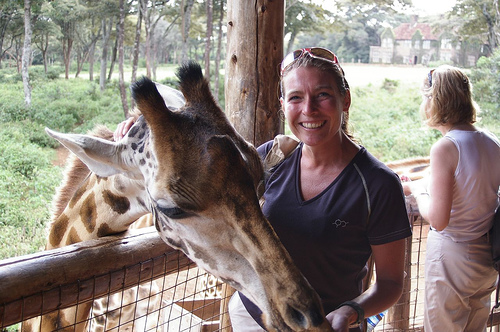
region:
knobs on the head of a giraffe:
[130, 60, 220, 132]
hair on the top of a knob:
[176, 60, 200, 80]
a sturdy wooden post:
[224, 0, 284, 147]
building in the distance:
[365, 23, 476, 65]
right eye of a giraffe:
[150, 193, 197, 223]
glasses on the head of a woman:
[280, 45, 345, 99]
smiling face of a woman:
[283, 47, 345, 145]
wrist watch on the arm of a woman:
[342, 298, 363, 325]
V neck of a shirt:
[295, 138, 364, 210]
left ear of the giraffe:
[41, 126, 128, 180]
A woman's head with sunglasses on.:
[271, 39, 368, 151]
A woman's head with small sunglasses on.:
[279, 44, 361, 151]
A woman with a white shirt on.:
[410, 60, 497, 330]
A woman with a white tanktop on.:
[413, 60, 499, 330]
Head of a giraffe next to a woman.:
[95, 51, 330, 329]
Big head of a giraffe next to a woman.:
[73, 57, 330, 329]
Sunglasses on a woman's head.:
[270, 42, 350, 72]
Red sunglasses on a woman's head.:
[268, 41, 350, 70]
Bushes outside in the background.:
[21, 92, 91, 116]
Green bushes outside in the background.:
[35, 92, 108, 119]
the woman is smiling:
[264, 53, 350, 191]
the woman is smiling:
[226, 15, 374, 182]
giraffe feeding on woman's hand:
[120, 68, 355, 328]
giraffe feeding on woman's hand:
[259, 280, 351, 330]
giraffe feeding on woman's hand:
[227, 118, 432, 330]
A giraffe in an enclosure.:
[13, 16, 474, 324]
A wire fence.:
[11, 213, 442, 328]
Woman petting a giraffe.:
[35, 36, 410, 327]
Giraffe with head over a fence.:
[26, 44, 317, 328]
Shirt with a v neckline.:
[243, 30, 406, 328]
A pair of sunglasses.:
[256, 40, 364, 147]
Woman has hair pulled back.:
[252, 26, 382, 176]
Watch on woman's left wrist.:
[329, 292, 382, 330]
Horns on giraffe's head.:
[125, 56, 217, 145]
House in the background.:
[354, 12, 471, 74]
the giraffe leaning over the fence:
[41, 60, 338, 328]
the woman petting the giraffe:
[246, 38, 430, 330]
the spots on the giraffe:
[58, 177, 123, 227]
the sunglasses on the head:
[275, 48, 347, 79]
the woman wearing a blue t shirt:
[236, 125, 424, 327]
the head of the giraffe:
[30, 73, 324, 330]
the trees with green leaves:
[41, 5, 129, 56]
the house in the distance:
[374, 18, 485, 60]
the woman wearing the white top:
[397, 70, 498, 274]